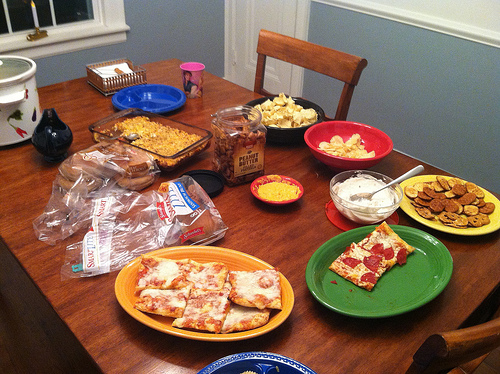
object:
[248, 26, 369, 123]
chair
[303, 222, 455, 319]
plate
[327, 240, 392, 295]
pizza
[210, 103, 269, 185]
container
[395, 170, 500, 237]
plate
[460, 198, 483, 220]
crakers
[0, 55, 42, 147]
rice cooker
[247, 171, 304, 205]
bowl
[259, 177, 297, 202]
mustard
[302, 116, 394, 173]
bowl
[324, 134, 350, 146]
chips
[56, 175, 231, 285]
bag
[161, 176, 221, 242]
buns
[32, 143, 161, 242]
bag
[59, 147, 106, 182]
buns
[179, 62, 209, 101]
cup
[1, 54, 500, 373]
table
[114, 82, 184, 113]
plate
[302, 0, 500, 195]
wall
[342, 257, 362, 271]
pepperoni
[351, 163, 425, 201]
spoon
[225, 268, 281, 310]
pizza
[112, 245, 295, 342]
plate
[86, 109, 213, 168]
pan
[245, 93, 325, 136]
bowl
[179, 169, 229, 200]
lid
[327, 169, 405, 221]
bowl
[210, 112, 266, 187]
peanuts